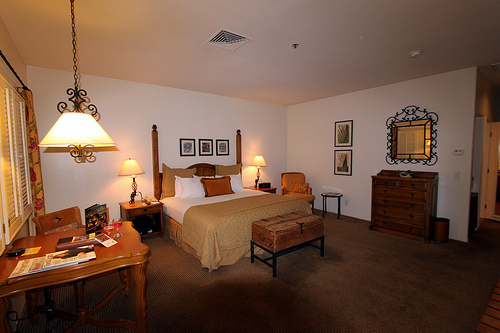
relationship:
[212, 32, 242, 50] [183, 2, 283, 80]
vent on ceiling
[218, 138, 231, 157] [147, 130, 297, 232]
picture above bed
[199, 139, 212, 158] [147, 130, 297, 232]
picture above bed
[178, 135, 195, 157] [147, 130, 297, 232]
picture above bed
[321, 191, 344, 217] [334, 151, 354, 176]
table under picture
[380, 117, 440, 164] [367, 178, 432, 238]
mirror above dresser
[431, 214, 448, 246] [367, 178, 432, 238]
can by dresser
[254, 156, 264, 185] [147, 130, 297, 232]
lamp by bed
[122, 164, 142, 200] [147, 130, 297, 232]
lamp by bed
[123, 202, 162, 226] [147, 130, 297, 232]
stand by bed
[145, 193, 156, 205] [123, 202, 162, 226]
phone on stand